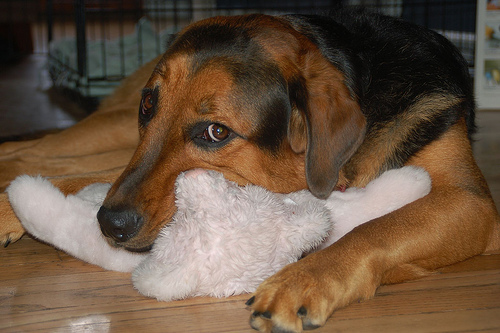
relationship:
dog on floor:
[0, 9, 499, 331] [3, 108, 499, 329]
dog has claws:
[0, 9, 499, 331] [244, 293, 307, 322]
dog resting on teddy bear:
[0, 9, 499, 331] [6, 161, 431, 301]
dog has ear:
[0, 9, 499, 331] [290, 71, 368, 199]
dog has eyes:
[0, 9, 499, 331] [140, 89, 245, 151]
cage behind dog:
[43, 4, 475, 107] [0, 9, 499, 331]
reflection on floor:
[61, 312, 116, 332] [3, 108, 499, 329]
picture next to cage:
[474, 2, 500, 114] [43, 4, 475, 107]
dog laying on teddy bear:
[0, 9, 499, 331] [6, 161, 431, 301]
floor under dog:
[3, 108, 499, 329] [0, 9, 499, 331]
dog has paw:
[0, 9, 499, 331] [245, 246, 366, 330]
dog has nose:
[0, 9, 499, 331] [97, 206, 133, 241]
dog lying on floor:
[0, 9, 499, 331] [3, 108, 499, 329]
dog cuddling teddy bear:
[0, 9, 499, 331] [6, 161, 431, 301]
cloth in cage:
[52, 21, 173, 96] [43, 4, 475, 107]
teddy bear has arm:
[6, 161, 431, 301] [7, 173, 140, 272]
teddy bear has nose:
[6, 161, 431, 301] [181, 166, 210, 183]